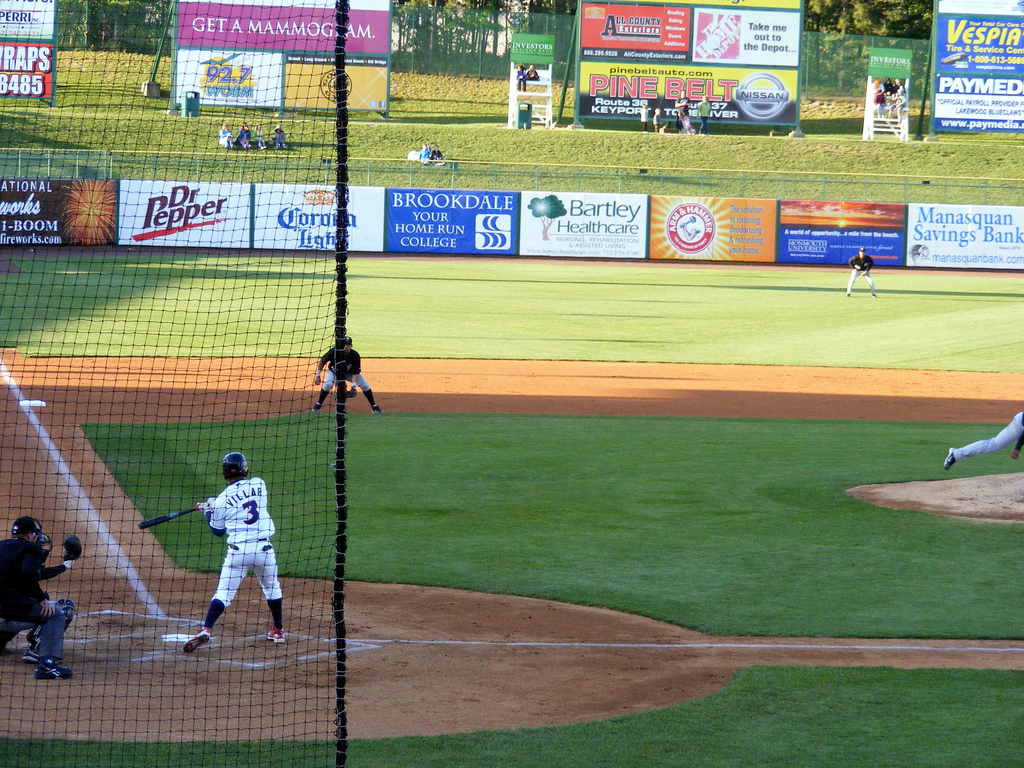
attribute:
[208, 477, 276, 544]
jersey — white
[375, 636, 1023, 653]
line — white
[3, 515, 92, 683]
umpire — behind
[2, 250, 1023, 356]
grass — green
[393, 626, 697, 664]
line — white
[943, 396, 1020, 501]
pant — white, pant leg 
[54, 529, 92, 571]
mitt — black